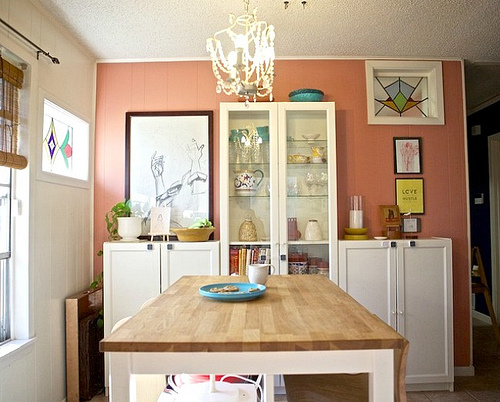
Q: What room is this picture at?
A: It is at the dining room.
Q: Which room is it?
A: It is a dining room.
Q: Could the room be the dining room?
A: Yes, it is the dining room.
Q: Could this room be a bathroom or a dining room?
A: It is a dining room.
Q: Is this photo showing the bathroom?
A: No, the picture is showing the dining room.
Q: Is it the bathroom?
A: No, it is the dining room.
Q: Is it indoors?
A: Yes, it is indoors.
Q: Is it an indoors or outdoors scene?
A: It is indoors.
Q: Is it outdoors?
A: No, it is indoors.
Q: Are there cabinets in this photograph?
A: Yes, there is a cabinet.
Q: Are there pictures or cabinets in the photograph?
A: Yes, there is a cabinet.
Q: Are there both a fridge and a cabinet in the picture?
A: No, there is a cabinet but no refrigerators.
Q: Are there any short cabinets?
A: Yes, there is a short cabinet.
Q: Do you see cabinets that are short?
A: Yes, there is a cabinet that is short.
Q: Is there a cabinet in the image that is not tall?
A: Yes, there is a short cabinet.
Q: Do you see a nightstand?
A: No, there are no nightstands.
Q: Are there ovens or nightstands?
A: No, there are no nightstands or ovens.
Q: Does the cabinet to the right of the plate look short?
A: Yes, the cabinet is short.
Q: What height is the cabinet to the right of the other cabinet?
A: The cabinet is short.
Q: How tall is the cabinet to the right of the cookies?
A: The cabinet is short.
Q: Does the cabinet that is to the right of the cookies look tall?
A: No, the cabinet is short.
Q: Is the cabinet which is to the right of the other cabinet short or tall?
A: The cabinet is short.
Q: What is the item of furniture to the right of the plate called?
A: The piece of furniture is a cabinet.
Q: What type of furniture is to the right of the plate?
A: The piece of furniture is a cabinet.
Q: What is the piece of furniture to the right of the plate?
A: The piece of furniture is a cabinet.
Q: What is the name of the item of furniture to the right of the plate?
A: The piece of furniture is a cabinet.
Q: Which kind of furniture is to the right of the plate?
A: The piece of furniture is a cabinet.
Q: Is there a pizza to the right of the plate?
A: No, there is a cabinet to the right of the plate.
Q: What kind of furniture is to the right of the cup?
A: The piece of furniture is a cabinet.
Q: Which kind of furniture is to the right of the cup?
A: The piece of furniture is a cabinet.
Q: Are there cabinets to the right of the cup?
A: Yes, there is a cabinet to the right of the cup.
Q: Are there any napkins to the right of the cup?
A: No, there is a cabinet to the right of the cup.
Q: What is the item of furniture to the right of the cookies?
A: The piece of furniture is a cabinet.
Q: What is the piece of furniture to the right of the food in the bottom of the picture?
A: The piece of furniture is a cabinet.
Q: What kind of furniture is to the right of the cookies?
A: The piece of furniture is a cabinet.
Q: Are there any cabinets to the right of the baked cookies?
A: Yes, there is a cabinet to the right of the cookies.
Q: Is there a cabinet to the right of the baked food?
A: Yes, there is a cabinet to the right of the cookies.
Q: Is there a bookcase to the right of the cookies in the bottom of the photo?
A: No, there is a cabinet to the right of the cookies.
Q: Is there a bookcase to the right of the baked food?
A: No, there is a cabinet to the right of the cookies.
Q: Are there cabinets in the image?
A: Yes, there is a cabinet.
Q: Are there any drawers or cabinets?
A: Yes, there is a cabinet.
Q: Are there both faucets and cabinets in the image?
A: No, there is a cabinet but no faucets.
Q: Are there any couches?
A: No, there are no couches.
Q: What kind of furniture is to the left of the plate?
A: The piece of furniture is a cabinet.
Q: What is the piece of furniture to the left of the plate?
A: The piece of furniture is a cabinet.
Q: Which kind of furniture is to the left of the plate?
A: The piece of furniture is a cabinet.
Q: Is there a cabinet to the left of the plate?
A: Yes, there is a cabinet to the left of the plate.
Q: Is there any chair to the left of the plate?
A: No, there is a cabinet to the left of the plate.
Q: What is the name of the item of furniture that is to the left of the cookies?
A: The piece of furniture is a cabinet.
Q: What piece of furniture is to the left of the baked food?
A: The piece of furniture is a cabinet.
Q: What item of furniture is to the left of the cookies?
A: The piece of furniture is a cabinet.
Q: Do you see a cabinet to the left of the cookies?
A: Yes, there is a cabinet to the left of the cookies.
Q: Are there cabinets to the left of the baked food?
A: Yes, there is a cabinet to the left of the cookies.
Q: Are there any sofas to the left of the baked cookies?
A: No, there is a cabinet to the left of the cookies.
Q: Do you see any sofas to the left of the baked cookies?
A: No, there is a cabinet to the left of the cookies.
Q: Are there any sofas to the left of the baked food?
A: No, there is a cabinet to the left of the cookies.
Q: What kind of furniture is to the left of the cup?
A: The piece of furniture is a cabinet.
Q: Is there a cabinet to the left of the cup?
A: Yes, there is a cabinet to the left of the cup.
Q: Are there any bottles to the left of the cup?
A: No, there is a cabinet to the left of the cup.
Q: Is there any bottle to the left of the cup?
A: No, there is a cabinet to the left of the cup.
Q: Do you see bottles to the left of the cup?
A: No, there is a cabinet to the left of the cup.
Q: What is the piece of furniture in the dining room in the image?
A: The piece of furniture is a cabinet.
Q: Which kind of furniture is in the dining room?
A: The piece of furniture is a cabinet.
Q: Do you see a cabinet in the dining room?
A: Yes, there is a cabinet in the dining room.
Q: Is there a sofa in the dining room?
A: No, there is a cabinet in the dining room.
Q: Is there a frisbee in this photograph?
A: No, there are no frisbees.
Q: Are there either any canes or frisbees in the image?
A: No, there are no frisbees or canes.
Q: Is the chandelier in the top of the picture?
A: Yes, the chandelier is in the top of the image.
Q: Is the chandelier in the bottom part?
A: No, the chandelier is in the top of the image.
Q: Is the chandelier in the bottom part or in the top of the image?
A: The chandelier is in the top of the image.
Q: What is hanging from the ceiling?
A: The chandelier is hanging from the ceiling.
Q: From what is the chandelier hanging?
A: The chandelier is hanging from the ceiling.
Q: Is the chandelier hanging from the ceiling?
A: Yes, the chandelier is hanging from the ceiling.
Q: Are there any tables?
A: Yes, there is a table.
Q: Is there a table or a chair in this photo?
A: Yes, there is a table.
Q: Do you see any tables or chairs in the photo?
A: Yes, there is a table.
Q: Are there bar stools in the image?
A: No, there are no bar stools.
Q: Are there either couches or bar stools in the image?
A: No, there are no bar stools or couches.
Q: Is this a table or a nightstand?
A: This is a table.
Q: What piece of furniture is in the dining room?
A: The piece of furniture is a table.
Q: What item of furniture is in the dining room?
A: The piece of furniture is a table.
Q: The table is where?
A: The table is in the dining room.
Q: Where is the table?
A: The table is in the dining room.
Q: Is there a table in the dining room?
A: Yes, there is a table in the dining room.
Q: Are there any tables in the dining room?
A: Yes, there is a table in the dining room.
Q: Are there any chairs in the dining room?
A: No, there is a table in the dining room.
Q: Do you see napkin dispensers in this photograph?
A: No, there are no napkin dispensers.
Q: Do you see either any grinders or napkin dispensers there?
A: No, there are no napkin dispensers or grinders.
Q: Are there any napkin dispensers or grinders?
A: No, there are no napkin dispensers or grinders.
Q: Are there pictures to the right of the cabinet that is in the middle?
A: Yes, there is a picture to the right of the cabinet.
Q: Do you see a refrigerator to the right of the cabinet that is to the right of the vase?
A: No, there is a picture to the right of the cabinet.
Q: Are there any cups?
A: Yes, there is a cup.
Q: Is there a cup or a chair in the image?
A: Yes, there is a cup.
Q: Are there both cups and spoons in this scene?
A: No, there is a cup but no spoons.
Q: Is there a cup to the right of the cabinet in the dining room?
A: Yes, there is a cup to the right of the cabinet.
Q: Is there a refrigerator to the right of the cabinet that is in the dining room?
A: No, there is a cup to the right of the cabinet.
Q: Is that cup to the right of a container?
A: No, the cup is to the right of the cabinet.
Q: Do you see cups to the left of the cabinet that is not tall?
A: Yes, there is a cup to the left of the cabinet.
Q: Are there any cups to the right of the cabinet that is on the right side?
A: No, the cup is to the left of the cabinet.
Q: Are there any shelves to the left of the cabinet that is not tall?
A: No, there is a cup to the left of the cabinet.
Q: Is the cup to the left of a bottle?
A: No, the cup is to the left of the cabinet.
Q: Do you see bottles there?
A: No, there are no bottles.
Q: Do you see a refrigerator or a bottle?
A: No, there are no bottles or refrigerators.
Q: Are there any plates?
A: Yes, there is a plate.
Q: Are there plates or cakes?
A: Yes, there is a plate.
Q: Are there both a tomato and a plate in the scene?
A: No, there is a plate but no tomatoes.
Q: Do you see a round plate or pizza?
A: Yes, there is a round plate.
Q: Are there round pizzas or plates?
A: Yes, there is a round plate.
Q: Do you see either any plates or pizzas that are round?
A: Yes, the plate is round.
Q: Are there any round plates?
A: Yes, there is a round plate.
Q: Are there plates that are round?
A: Yes, there is a plate that is round.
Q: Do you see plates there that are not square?
A: Yes, there is a round plate.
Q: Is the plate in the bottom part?
A: Yes, the plate is in the bottom of the image.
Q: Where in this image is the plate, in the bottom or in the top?
A: The plate is in the bottom of the image.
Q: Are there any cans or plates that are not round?
A: No, there is a plate but it is round.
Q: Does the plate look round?
A: Yes, the plate is round.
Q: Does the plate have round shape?
A: Yes, the plate is round.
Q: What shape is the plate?
A: The plate is round.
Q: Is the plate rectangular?
A: No, the plate is round.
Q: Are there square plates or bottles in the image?
A: No, there is a plate but it is round.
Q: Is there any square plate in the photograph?
A: No, there is a plate but it is round.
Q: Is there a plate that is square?
A: No, there is a plate but it is round.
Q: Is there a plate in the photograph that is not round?
A: No, there is a plate but it is round.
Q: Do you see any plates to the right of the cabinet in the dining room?
A: Yes, there is a plate to the right of the cabinet.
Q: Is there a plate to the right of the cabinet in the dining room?
A: Yes, there is a plate to the right of the cabinet.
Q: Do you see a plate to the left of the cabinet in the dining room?
A: No, the plate is to the right of the cabinet.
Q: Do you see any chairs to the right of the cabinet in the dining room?
A: No, there is a plate to the right of the cabinet.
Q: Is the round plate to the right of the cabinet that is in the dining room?
A: Yes, the plate is to the right of the cabinet.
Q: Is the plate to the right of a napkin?
A: No, the plate is to the right of the cabinet.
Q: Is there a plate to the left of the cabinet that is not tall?
A: Yes, there is a plate to the left of the cabinet.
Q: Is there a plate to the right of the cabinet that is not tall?
A: No, the plate is to the left of the cabinet.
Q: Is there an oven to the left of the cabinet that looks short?
A: No, there is a plate to the left of the cabinet.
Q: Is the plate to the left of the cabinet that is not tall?
A: Yes, the plate is to the left of the cabinet.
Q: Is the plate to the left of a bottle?
A: No, the plate is to the left of the cabinet.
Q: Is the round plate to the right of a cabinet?
A: No, the plate is to the left of a cabinet.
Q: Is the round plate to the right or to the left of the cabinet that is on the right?
A: The plate is to the left of the cabinet.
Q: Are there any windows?
A: Yes, there is a window.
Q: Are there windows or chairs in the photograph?
A: Yes, there is a window.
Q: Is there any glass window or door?
A: Yes, there is a glass window.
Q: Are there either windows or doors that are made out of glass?
A: Yes, the window is made of glass.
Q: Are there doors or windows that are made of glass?
A: Yes, the window is made of glass.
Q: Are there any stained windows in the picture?
A: Yes, there is a stained window.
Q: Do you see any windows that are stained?
A: Yes, there is a window that is stained.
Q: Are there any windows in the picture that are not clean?
A: Yes, there is a stained window.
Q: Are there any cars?
A: No, there are no cars.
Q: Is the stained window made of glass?
A: Yes, the window is made of glass.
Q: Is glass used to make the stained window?
A: Yes, the window is made of glass.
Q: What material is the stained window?
A: The window is made of glass.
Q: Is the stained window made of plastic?
A: No, the window is made of glass.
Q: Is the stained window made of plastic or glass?
A: The window is made of glass.